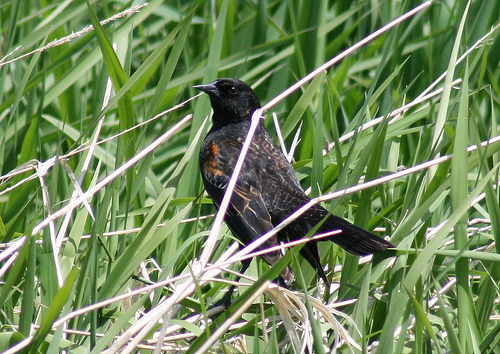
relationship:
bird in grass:
[191, 78, 396, 314] [0, 1, 499, 354]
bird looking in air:
[191, 78, 396, 314] [1, 2, 499, 73]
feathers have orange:
[197, 117, 297, 286] [201, 139, 227, 176]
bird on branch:
[191, 78, 396, 314] [153, 297, 242, 345]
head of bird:
[190, 77, 263, 118] [191, 78, 396, 314]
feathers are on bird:
[197, 117, 297, 286] [191, 78, 396, 314]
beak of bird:
[192, 81, 219, 98] [191, 78, 396, 314]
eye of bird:
[227, 85, 237, 94] [191, 78, 396, 314]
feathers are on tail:
[197, 117, 297, 286] [310, 197, 396, 262]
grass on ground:
[0, 1, 499, 354] [1, 218, 499, 352]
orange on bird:
[201, 139, 227, 176] [191, 78, 396, 314]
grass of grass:
[0, 1, 499, 354] [83, 1, 152, 352]